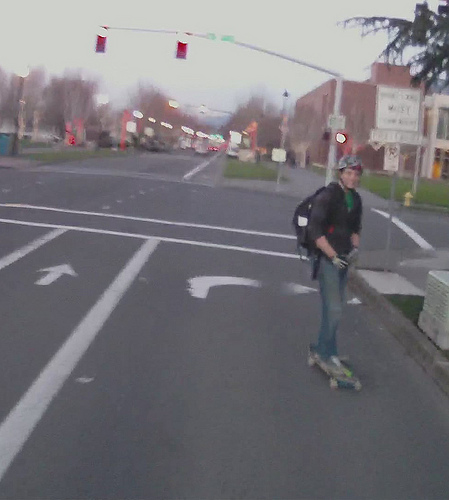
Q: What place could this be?
A: It is a road.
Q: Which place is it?
A: It is a road.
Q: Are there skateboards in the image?
A: Yes, there is a skateboard.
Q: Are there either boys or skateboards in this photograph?
A: Yes, there is a skateboard.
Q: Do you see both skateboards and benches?
A: No, there is a skateboard but no benches.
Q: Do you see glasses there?
A: No, there are no glasses.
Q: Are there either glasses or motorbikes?
A: No, there are no glasses or motorbikes.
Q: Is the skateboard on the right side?
A: Yes, the skateboard is on the right of the image.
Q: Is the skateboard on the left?
A: No, the skateboard is on the right of the image.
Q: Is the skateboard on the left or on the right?
A: The skateboard is on the right of the image.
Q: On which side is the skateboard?
A: The skateboard is on the right of the image.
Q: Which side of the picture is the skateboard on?
A: The skateboard is on the right of the image.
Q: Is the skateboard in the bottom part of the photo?
A: Yes, the skateboard is in the bottom of the image.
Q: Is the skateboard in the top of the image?
A: No, the skateboard is in the bottom of the image.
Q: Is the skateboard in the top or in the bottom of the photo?
A: The skateboard is in the bottom of the image.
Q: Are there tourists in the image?
A: No, there are no tourists.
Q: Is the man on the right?
A: Yes, the man is on the right of the image.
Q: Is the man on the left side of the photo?
A: No, the man is on the right of the image.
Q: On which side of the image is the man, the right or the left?
A: The man is on the right of the image.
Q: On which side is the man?
A: The man is on the right of the image.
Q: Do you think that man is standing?
A: Yes, the man is standing.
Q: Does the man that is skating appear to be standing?
A: Yes, the man is standing.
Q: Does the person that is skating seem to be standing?
A: Yes, the man is standing.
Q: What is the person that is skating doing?
A: The man is standing.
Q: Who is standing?
A: The man is standing.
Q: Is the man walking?
A: No, the man is standing.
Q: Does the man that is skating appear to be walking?
A: No, the man is standing.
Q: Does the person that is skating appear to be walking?
A: No, the man is standing.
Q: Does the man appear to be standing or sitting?
A: The man is standing.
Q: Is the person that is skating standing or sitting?
A: The man is standing.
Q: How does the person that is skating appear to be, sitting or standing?
A: The man is standing.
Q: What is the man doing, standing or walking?
A: The man is standing.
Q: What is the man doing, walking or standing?
A: The man is standing.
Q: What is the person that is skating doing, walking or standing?
A: The man is standing.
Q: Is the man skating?
A: Yes, the man is skating.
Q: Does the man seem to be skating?
A: Yes, the man is skating.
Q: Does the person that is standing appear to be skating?
A: Yes, the man is skating.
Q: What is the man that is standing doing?
A: The man is skating.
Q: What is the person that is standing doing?
A: The man is skating.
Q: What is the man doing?
A: The man is skating.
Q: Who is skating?
A: The man is skating.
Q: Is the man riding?
A: No, the man is skating.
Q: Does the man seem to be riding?
A: No, the man is skating.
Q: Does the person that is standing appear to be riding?
A: No, the man is skating.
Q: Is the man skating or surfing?
A: The man is skating.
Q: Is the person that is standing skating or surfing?
A: The man is skating.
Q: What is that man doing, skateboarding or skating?
A: The man is skating.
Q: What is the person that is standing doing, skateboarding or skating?
A: The man is skating.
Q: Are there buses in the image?
A: No, there are no buses.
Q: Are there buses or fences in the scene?
A: No, there are no buses or fences.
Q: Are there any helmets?
A: Yes, there is a helmet.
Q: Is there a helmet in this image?
A: Yes, there is a helmet.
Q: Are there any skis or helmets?
A: Yes, there is a helmet.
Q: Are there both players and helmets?
A: No, there is a helmet but no players.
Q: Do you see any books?
A: No, there are no books.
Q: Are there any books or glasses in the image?
A: No, there are no books or glasses.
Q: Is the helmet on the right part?
A: Yes, the helmet is on the right of the image.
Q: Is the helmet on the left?
A: No, the helmet is on the right of the image.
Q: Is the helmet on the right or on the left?
A: The helmet is on the right of the image.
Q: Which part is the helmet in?
A: The helmet is on the right of the image.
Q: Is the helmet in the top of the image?
A: Yes, the helmet is in the top of the image.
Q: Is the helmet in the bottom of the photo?
A: No, the helmet is in the top of the image.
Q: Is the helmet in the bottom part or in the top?
A: The helmet is in the top of the image.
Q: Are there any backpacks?
A: Yes, there is a backpack.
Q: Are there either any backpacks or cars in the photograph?
A: Yes, there is a backpack.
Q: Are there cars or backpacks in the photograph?
A: Yes, there is a backpack.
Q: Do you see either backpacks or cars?
A: Yes, there is a backpack.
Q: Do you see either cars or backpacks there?
A: Yes, there is a backpack.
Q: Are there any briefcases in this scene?
A: No, there are no briefcases.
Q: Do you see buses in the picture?
A: No, there are no buses.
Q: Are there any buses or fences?
A: No, there are no buses or fences.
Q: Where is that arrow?
A: The arrow is on the road.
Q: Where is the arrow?
A: The arrow is on the road.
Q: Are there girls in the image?
A: No, there are no girls.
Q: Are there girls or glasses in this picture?
A: No, there are no girls or glasses.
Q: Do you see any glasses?
A: No, there are no glasses.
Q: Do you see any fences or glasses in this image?
A: No, there are no glasses or fences.